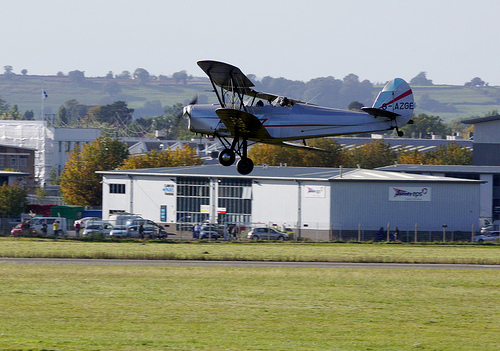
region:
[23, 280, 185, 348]
Green Grass on a field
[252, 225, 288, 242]
A small grey car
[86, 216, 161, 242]
A group of cars in the parking lot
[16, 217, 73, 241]
A van with people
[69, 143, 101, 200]
A large tree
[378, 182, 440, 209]
The sign of a building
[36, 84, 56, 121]
A flag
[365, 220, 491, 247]
A fence by the building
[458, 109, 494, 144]
The roof of a building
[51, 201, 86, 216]
A green container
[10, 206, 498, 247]
the fence surrounds the building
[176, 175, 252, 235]
the building has windows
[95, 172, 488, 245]
the building is white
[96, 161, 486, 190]
the building has a grey roof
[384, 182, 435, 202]
the sign is on the side of the building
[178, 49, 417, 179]
the plane is silver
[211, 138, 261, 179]
the plane has landing gear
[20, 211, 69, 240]
the van is white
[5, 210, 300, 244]
the parking lot is full of cars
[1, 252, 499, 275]
the runway is paved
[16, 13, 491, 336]
Picture is taken outside.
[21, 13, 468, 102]
Picture is taken during the day.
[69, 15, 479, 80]
The sky is bright grey in color.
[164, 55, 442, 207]
A plane is off the ground.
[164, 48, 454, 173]
The plane has two wings.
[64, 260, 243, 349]
The grass is green.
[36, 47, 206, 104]
Trees appear on the hills.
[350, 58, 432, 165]
The plane's tail says A206.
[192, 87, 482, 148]
The plane has a grey body.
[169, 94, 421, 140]
A red stripe is seen on the plane.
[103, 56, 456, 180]
a plane about to land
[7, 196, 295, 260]
cars in the parking lot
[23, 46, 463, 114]
a rising hill behind the airport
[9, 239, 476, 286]
the airport runway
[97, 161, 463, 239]
a white building with windowed doors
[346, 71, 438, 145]
the tailfin of the plane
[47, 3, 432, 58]
grey clouds over the hill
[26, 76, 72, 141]
a flagpole on a white building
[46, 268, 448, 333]
grass next to the runway in the foreground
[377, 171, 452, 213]
the sign on the side of the building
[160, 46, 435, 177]
Plane is flying low.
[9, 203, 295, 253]
Cars in a parking lot.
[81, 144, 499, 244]
Building has one floor.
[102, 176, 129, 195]
Small windows on left of building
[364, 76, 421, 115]
Vertical stabilizer on plane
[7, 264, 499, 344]
Field covers with green grass.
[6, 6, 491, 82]
Sky is cloudy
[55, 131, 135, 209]
Tree near the building.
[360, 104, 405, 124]
Horizontal stabilizer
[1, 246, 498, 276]
Road in center of green grass.